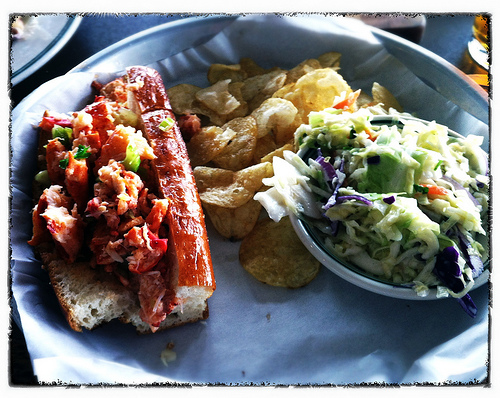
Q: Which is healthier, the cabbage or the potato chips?
A: The cabbage is healthier than the potato chips.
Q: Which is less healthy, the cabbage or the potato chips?
A: The potato chips is less healthy than the cabbage.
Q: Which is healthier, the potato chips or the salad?
A: The salad is healthier than the potato chips.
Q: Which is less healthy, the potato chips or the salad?
A: The potato chips is less healthy than the salad.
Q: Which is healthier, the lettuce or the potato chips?
A: The lettuce is healthier than the potato chips.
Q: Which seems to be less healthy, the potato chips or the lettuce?
A: The potato chips is less healthy than the lettuce.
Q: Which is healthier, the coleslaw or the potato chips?
A: The coleslaw is healthier than the potato chips.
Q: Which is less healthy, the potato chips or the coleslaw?
A: The potato chips is less healthy than the coleslaw.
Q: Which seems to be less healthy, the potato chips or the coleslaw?
A: The potato chips is less healthy than the coleslaw.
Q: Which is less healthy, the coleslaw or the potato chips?
A: The potato chips is less healthy than the coleslaw.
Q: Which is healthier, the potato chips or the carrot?
A: The carrot is healthier than the potato chips.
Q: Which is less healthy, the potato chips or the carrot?
A: The potato chips is less healthy than the carrot.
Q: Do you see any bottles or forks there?
A: No, there are no forks or bottles.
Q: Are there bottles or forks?
A: No, there are no forks or bottles.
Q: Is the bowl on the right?
A: Yes, the bowl is on the right of the image.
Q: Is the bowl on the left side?
A: No, the bowl is on the right of the image.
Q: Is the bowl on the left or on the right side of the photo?
A: The bowl is on the right of the image.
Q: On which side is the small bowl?
A: The bowl is on the right of the image.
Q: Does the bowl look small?
A: Yes, the bowl is small.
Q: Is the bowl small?
A: Yes, the bowl is small.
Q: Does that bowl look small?
A: Yes, the bowl is small.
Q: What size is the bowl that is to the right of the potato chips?
A: The bowl is small.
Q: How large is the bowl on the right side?
A: The bowl is small.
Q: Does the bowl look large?
A: No, the bowl is small.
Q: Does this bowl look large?
A: No, the bowl is small.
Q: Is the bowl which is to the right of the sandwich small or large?
A: The bowl is small.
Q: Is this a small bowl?
A: Yes, this is a small bowl.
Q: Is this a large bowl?
A: No, this is a small bowl.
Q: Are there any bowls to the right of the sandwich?
A: Yes, there is a bowl to the right of the sandwich.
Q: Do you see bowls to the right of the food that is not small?
A: Yes, there is a bowl to the right of the sandwich.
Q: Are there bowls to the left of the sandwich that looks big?
A: No, the bowl is to the right of the sandwich.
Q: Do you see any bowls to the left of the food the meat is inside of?
A: No, the bowl is to the right of the sandwich.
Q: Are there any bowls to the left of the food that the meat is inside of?
A: No, the bowl is to the right of the sandwich.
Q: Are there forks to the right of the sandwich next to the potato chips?
A: No, there is a bowl to the right of the sandwich.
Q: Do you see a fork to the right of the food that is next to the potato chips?
A: No, there is a bowl to the right of the sandwich.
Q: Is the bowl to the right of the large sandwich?
A: Yes, the bowl is to the right of the sandwich.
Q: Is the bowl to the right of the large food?
A: Yes, the bowl is to the right of the sandwich.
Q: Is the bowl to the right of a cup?
A: No, the bowl is to the right of the sandwich.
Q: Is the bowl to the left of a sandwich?
A: No, the bowl is to the right of a sandwich.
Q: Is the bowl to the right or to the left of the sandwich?
A: The bowl is to the right of the sandwich.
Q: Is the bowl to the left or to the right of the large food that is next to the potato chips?
A: The bowl is to the right of the sandwich.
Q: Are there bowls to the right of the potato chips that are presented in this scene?
A: Yes, there is a bowl to the right of the potato chips.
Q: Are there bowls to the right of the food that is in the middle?
A: Yes, there is a bowl to the right of the potato chips.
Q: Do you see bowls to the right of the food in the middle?
A: Yes, there is a bowl to the right of the potato chips.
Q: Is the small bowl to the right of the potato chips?
A: Yes, the bowl is to the right of the potato chips.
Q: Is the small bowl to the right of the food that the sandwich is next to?
A: Yes, the bowl is to the right of the potato chips.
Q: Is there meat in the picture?
A: Yes, there is meat.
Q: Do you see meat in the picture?
A: Yes, there is meat.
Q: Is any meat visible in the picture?
A: Yes, there is meat.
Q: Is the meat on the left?
A: Yes, the meat is on the left of the image.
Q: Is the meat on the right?
A: No, the meat is on the left of the image.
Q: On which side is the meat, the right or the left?
A: The meat is on the left of the image.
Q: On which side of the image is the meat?
A: The meat is on the left of the image.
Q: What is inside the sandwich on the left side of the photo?
A: The meat is inside the sandwich.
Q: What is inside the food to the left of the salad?
A: The meat is inside the sandwich.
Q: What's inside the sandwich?
A: The meat is inside the sandwich.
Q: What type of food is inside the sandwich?
A: The food is meat.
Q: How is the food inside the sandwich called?
A: The food is meat.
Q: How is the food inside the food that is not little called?
A: The food is meat.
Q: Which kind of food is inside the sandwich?
A: The food is meat.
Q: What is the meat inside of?
A: The meat is inside the sandwich.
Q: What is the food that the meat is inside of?
A: The food is a sandwich.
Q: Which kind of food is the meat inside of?
A: The meat is inside the sandwich.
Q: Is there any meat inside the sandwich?
A: Yes, there is meat inside the sandwich.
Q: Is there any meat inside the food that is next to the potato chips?
A: Yes, there is meat inside the sandwich.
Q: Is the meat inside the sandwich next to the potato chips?
A: Yes, the meat is inside the sandwich.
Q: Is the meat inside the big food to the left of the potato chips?
A: Yes, the meat is inside the sandwich.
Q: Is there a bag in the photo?
A: No, there are no bags.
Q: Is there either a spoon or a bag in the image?
A: No, there are no bags or spoons.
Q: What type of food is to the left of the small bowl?
A: The food is potato chips.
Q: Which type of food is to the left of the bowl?
A: The food is potato chips.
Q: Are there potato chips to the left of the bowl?
A: Yes, there are potato chips to the left of the bowl.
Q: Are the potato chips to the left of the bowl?
A: Yes, the potato chips are to the left of the bowl.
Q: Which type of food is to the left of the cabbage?
A: The food is potato chips.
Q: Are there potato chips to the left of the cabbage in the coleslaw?
A: Yes, there are potato chips to the left of the cabbage.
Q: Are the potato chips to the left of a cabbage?
A: Yes, the potato chips are to the left of a cabbage.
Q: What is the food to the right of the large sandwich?
A: The food is potato chips.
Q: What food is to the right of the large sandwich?
A: The food is potato chips.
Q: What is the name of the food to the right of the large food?
A: The food is potato chips.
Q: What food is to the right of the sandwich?
A: The food is potato chips.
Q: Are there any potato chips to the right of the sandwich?
A: Yes, there are potato chips to the right of the sandwich.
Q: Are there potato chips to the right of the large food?
A: Yes, there are potato chips to the right of the sandwich.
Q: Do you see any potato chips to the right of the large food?
A: Yes, there are potato chips to the right of the sandwich.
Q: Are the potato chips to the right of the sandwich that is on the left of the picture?
A: Yes, the potato chips are to the right of the sandwich.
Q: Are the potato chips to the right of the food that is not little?
A: Yes, the potato chips are to the right of the sandwich.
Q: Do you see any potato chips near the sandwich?
A: Yes, there are potato chips near the sandwich.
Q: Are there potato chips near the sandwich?
A: Yes, there are potato chips near the sandwich.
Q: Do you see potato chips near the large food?
A: Yes, there are potato chips near the sandwich.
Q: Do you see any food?
A: Yes, there is food.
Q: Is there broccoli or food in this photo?
A: Yes, there is food.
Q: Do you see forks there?
A: No, there are no forks.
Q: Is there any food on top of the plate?
A: Yes, there is food on top of the plate.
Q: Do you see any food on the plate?
A: Yes, there is food on the plate.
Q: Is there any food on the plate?
A: Yes, there is food on the plate.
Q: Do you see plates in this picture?
A: Yes, there is a plate.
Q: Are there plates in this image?
A: Yes, there is a plate.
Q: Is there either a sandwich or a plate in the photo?
A: Yes, there is a plate.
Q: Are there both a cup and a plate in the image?
A: No, there is a plate but no cups.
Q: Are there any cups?
A: No, there are no cups.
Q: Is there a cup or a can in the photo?
A: No, there are no cups or cans.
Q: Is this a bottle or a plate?
A: This is a plate.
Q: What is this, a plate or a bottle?
A: This is a plate.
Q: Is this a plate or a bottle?
A: This is a plate.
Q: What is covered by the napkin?
A: The plate is covered by the napkin.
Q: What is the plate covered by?
A: The plate is covered by the napkin.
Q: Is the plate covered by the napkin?
A: Yes, the plate is covered by the napkin.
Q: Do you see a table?
A: Yes, there is a table.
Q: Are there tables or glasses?
A: Yes, there is a table.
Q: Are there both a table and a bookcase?
A: No, there is a table but no bookcases.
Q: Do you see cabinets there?
A: No, there are no cabinets.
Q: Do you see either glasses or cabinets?
A: No, there are no cabinets or glasses.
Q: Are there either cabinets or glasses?
A: No, there are no cabinets or glasses.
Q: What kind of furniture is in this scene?
A: The furniture is a table.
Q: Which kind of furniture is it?
A: The piece of furniture is a table.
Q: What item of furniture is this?
A: This is a table.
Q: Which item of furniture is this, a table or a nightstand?
A: This is a table.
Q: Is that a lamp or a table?
A: That is a table.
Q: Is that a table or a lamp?
A: That is a table.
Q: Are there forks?
A: No, there are no forks.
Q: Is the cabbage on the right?
A: Yes, the cabbage is on the right of the image.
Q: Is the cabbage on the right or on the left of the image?
A: The cabbage is on the right of the image.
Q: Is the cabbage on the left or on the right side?
A: The cabbage is on the right of the image.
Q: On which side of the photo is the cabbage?
A: The cabbage is on the right of the image.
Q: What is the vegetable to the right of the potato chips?
A: The vegetable is a cabbage.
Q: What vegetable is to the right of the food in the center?
A: The vegetable is a cabbage.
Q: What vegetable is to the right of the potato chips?
A: The vegetable is a cabbage.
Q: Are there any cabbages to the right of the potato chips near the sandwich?
A: Yes, there is a cabbage to the right of the potato chips.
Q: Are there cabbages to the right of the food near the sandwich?
A: Yes, there is a cabbage to the right of the potato chips.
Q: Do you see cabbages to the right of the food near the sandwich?
A: Yes, there is a cabbage to the right of the potato chips.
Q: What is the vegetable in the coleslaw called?
A: The vegetable is a cabbage.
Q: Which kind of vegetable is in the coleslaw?
A: The vegetable is a cabbage.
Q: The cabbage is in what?
A: The cabbage is in the coleslaw.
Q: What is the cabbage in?
A: The cabbage is in the coleslaw.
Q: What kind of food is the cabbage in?
A: The cabbage is in the coleslaw.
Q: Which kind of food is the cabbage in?
A: The cabbage is in the coleslaw.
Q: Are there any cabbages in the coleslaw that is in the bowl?
A: Yes, there is a cabbage in the coleslaw.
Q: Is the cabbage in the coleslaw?
A: Yes, the cabbage is in the coleslaw.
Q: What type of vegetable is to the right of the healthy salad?
A: The vegetable is a cabbage.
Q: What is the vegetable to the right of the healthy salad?
A: The vegetable is a cabbage.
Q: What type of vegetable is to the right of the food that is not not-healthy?
A: The vegetable is a cabbage.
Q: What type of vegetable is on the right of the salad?
A: The vegetable is a cabbage.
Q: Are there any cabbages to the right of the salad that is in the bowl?
A: Yes, there is a cabbage to the right of the salad.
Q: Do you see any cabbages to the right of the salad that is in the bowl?
A: Yes, there is a cabbage to the right of the salad.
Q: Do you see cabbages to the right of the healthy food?
A: Yes, there is a cabbage to the right of the salad.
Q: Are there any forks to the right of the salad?
A: No, there is a cabbage to the right of the salad.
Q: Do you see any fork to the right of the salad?
A: No, there is a cabbage to the right of the salad.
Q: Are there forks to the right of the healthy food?
A: No, there is a cabbage to the right of the salad.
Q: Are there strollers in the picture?
A: No, there are no strollers.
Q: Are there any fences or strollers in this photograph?
A: No, there are no strollers or fences.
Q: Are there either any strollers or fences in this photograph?
A: No, there are no strollers or fences.